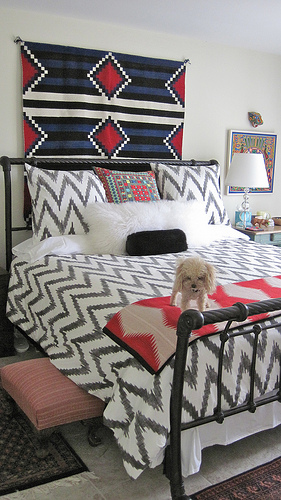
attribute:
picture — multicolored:
[226, 130, 277, 193]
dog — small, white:
[152, 255, 233, 305]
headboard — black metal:
[61, 127, 239, 167]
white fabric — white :
[82, 196, 205, 232]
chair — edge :
[44, 395, 50, 413]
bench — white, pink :
[8, 356, 100, 430]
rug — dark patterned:
[4, 384, 94, 498]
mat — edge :
[5, 394, 102, 493]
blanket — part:
[100, 248, 278, 379]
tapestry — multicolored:
[18, 36, 190, 226]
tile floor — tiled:
[10, 425, 280, 495]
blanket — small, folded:
[102, 275, 279, 375]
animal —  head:
[165, 252, 221, 318]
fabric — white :
[20, 32, 193, 165]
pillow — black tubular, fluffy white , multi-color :
[95, 161, 218, 245]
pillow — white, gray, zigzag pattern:
[152, 160, 227, 226]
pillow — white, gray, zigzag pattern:
[27, 161, 103, 240]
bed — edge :
[5, 160, 279, 494]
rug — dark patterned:
[186, 456, 280, 495]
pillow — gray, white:
[19, 160, 109, 245]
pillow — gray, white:
[149, 154, 236, 229]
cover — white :
[6, 237, 280, 479]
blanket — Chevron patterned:
[6, 238, 280, 477]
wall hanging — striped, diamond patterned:
[12, 35, 189, 159]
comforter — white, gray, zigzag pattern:
[6, 238, 280, 479]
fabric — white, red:
[103, 275, 280, 376]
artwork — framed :
[171, 314, 263, 498]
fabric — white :
[48, 242, 70, 251]